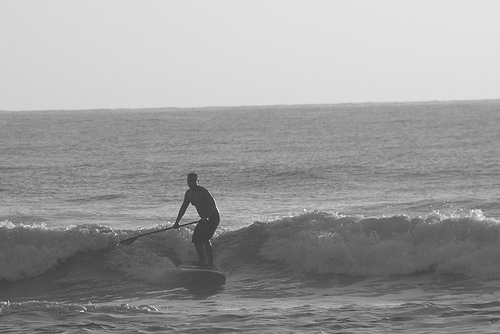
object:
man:
[170, 171, 224, 269]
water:
[310, 165, 443, 276]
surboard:
[179, 264, 227, 284]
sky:
[174, 10, 280, 60]